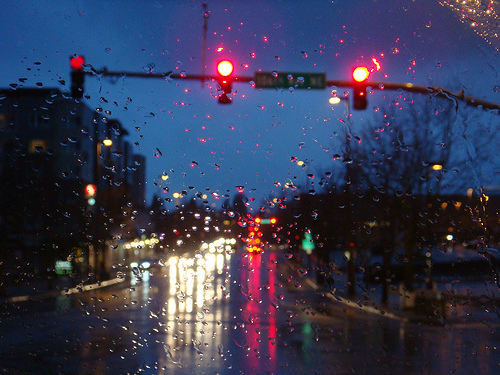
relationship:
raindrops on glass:
[2, 0, 497, 371] [2, 0, 499, 370]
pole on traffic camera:
[115, 61, 352, 112] [198, 6, 228, 83]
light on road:
[212, 51, 244, 109] [227, 293, 322, 368]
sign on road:
[252, 67, 329, 92] [190, 243, 282, 365]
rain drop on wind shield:
[160, 166, 207, 211] [0, 0, 499, 374]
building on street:
[66, 92, 165, 234] [45, 250, 185, 320]